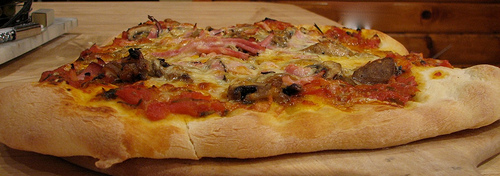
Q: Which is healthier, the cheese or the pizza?
A: The cheese is healthier than the pizza.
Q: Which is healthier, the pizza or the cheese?
A: The cheese is healthier than the pizza.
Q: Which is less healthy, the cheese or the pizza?
A: The pizza is less healthy than the cheese.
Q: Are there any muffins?
A: No, there are no muffins.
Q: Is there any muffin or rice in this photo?
A: No, there are no muffins or rice.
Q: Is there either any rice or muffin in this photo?
A: No, there are no muffins or rice.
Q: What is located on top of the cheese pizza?
A: The mushroom is on top of the pizza.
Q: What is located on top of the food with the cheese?
A: The mushroom is on top of the pizza.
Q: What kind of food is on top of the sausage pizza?
A: The food is a mushroom.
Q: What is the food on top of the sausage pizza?
A: The food is a mushroom.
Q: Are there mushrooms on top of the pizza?
A: Yes, there is a mushroom on top of the pizza.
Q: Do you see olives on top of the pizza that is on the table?
A: No, there is a mushroom on top of the pizza.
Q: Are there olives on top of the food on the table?
A: No, there is a mushroom on top of the pizza.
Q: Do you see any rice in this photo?
A: No, there is no rice.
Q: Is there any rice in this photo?
A: No, there is no rice.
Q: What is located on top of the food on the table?
A: The mushroom is on top of the pizza.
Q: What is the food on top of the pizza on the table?
A: The food is a mushroom.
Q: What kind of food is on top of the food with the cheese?
A: The food is a mushroom.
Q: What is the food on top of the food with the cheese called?
A: The food is a mushroom.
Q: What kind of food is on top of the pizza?
A: The food is a mushroom.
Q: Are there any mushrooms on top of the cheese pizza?
A: Yes, there is a mushroom on top of the pizza.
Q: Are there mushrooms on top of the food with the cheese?
A: Yes, there is a mushroom on top of the pizza.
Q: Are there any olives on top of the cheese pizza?
A: No, there is a mushroom on top of the pizza.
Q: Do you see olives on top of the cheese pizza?
A: No, there is a mushroom on top of the pizza.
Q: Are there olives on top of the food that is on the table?
A: No, there is a mushroom on top of the pizza.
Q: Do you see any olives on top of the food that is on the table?
A: No, there is a mushroom on top of the pizza.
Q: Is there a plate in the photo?
A: No, there are no plates.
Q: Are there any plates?
A: No, there are no plates.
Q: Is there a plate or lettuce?
A: No, there are no plates or lettuce.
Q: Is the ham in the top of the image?
A: Yes, the ham is in the top of the image.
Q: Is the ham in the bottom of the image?
A: No, the ham is in the top of the image.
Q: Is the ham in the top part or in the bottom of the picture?
A: The ham is in the top of the image.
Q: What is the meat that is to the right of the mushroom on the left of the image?
A: The meat is ham.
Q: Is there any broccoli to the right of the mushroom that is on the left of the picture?
A: No, there is ham to the right of the mushroom.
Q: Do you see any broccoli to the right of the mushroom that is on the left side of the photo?
A: No, there is ham to the right of the mushroom.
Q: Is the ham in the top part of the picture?
A: Yes, the ham is in the top of the image.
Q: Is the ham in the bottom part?
A: No, the ham is in the top of the image.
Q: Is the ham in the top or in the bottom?
A: The ham is in the top of the image.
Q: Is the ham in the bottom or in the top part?
A: The ham is in the top of the image.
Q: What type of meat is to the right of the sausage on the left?
A: The meat is ham.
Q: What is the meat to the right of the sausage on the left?
A: The meat is ham.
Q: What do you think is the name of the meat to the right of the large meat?
A: The meat is ham.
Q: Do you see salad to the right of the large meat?
A: No, there is ham to the right of the meat.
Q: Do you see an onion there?
A: No, there are no onions.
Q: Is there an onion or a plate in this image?
A: No, there are no onions or plates.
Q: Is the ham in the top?
A: Yes, the ham is in the top of the image.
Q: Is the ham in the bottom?
A: No, the ham is in the top of the image.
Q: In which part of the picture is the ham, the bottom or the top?
A: The ham is in the top of the image.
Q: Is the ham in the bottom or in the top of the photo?
A: The ham is in the top of the image.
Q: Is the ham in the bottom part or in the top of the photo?
A: The ham is in the top of the image.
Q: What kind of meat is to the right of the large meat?
A: The meat is ham.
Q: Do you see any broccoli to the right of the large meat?
A: No, there is ham to the right of the meat.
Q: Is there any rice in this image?
A: No, there is no rice.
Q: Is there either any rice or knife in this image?
A: No, there are no rice or knives.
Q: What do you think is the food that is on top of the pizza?
A: The food is a mushroom.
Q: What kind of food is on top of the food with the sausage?
A: The food is a mushroom.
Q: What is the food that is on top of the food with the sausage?
A: The food is a mushroom.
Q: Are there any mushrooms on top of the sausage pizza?
A: Yes, there is a mushroom on top of the pizza.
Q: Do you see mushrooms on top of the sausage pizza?
A: Yes, there is a mushroom on top of the pizza.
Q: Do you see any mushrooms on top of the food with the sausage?
A: Yes, there is a mushroom on top of the pizza.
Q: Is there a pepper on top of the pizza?
A: No, there is a mushroom on top of the pizza.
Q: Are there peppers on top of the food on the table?
A: No, there is a mushroom on top of the pizza.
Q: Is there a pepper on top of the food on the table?
A: No, there is a mushroom on top of the pizza.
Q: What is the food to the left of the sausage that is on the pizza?
A: The food is a mushroom.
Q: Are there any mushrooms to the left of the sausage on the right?
A: Yes, there is a mushroom to the left of the sausage.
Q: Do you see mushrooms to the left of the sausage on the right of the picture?
A: Yes, there is a mushroom to the left of the sausage.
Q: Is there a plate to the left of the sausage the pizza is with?
A: No, there is a mushroom to the left of the sausage.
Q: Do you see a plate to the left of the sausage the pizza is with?
A: No, there is a mushroom to the left of the sausage.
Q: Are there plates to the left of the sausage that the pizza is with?
A: No, there is a mushroom to the left of the sausage.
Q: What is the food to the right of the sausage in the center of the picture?
A: The food is a mushroom.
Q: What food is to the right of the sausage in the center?
A: The food is a mushroom.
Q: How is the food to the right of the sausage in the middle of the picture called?
A: The food is a mushroom.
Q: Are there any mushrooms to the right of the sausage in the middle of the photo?
A: Yes, there is a mushroom to the right of the sausage.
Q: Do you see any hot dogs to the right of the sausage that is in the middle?
A: No, there is a mushroom to the right of the sausage.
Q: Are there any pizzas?
A: Yes, there is a pizza.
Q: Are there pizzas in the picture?
A: Yes, there is a pizza.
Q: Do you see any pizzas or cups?
A: Yes, there is a pizza.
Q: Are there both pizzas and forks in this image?
A: No, there is a pizza but no forks.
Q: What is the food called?
A: The food is a pizza.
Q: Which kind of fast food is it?
A: The food is a pizza.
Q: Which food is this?
A: This is a pizza.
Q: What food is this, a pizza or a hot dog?
A: This is a pizza.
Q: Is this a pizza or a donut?
A: This is a pizza.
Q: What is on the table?
A: The pizza is on the table.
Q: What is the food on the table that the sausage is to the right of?
A: The food is a pizza.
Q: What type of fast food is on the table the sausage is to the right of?
A: The food is a pizza.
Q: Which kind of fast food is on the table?
A: The food is a pizza.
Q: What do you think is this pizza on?
A: The pizza is on the table.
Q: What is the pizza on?
A: The pizza is on the table.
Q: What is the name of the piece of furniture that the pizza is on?
A: The piece of furniture is a table.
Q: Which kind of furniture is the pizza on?
A: The pizza is on the table.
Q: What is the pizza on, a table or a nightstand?
A: The pizza is on a table.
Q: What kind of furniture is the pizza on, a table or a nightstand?
A: The pizza is on a table.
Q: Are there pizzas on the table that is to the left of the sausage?
A: Yes, there is a pizza on the table.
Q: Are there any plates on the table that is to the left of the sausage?
A: No, there is a pizza on the table.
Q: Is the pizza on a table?
A: Yes, the pizza is on a table.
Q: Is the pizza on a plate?
A: No, the pizza is on a table.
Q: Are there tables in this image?
A: Yes, there is a table.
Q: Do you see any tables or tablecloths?
A: Yes, there is a table.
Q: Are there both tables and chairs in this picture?
A: No, there is a table but no chairs.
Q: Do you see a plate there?
A: No, there are no plates.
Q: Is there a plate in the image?
A: No, there are no plates.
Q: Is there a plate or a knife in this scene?
A: No, there are no plates or knives.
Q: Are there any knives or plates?
A: No, there are no plates or knives.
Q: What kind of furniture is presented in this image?
A: The furniture is a table.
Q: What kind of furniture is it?
A: The piece of furniture is a table.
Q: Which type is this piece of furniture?
A: This is a table.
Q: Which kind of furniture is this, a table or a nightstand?
A: This is a table.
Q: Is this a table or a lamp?
A: This is a table.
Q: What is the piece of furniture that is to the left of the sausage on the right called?
A: The piece of furniture is a table.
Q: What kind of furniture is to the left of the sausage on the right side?
A: The piece of furniture is a table.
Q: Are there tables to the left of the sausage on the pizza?
A: Yes, there is a table to the left of the sausage.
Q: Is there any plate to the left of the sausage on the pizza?
A: No, there is a table to the left of the sausage.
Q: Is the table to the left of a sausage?
A: Yes, the table is to the left of a sausage.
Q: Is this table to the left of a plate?
A: No, the table is to the left of a sausage.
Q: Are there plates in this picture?
A: No, there are no plates.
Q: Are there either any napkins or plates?
A: No, there are no plates or napkins.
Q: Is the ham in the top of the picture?
A: Yes, the ham is in the top of the image.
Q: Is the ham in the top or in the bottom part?
A: The ham is in the top of the image.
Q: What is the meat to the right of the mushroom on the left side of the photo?
A: The meat is ham.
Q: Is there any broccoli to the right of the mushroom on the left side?
A: No, there is ham to the right of the mushroom.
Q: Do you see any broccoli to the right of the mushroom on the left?
A: No, there is ham to the right of the mushroom.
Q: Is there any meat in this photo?
A: Yes, there is meat.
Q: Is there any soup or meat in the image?
A: Yes, there is meat.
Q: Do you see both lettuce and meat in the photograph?
A: No, there is meat but no lettuce.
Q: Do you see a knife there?
A: No, there are no knives.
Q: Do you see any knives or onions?
A: No, there are no knives or onions.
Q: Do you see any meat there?
A: Yes, there is meat.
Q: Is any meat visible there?
A: Yes, there is meat.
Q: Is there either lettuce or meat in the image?
A: Yes, there is meat.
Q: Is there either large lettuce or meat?
A: Yes, there is large meat.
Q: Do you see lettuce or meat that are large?
A: Yes, the meat is large.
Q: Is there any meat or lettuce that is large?
A: Yes, the meat is large.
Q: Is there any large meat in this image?
A: Yes, there is large meat.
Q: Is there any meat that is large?
A: Yes, there is meat that is large.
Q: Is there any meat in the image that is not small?
A: Yes, there is large meat.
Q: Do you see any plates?
A: No, there are no plates.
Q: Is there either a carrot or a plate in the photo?
A: No, there are no plates or carrots.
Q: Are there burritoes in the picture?
A: No, there are no burritoes.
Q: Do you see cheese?
A: Yes, there is cheese.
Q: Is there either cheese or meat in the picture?
A: Yes, there is cheese.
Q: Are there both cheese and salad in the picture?
A: No, there is cheese but no salad.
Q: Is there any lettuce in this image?
A: No, there is no lettuce.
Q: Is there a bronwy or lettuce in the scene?
A: No, there are no lettuce or brownies.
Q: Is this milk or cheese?
A: This is cheese.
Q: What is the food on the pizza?
A: The food is cheese.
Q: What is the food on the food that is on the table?
A: The food is cheese.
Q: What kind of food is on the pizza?
A: The food is cheese.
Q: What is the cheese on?
A: The cheese is on the pizza.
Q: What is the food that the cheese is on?
A: The food is a pizza.